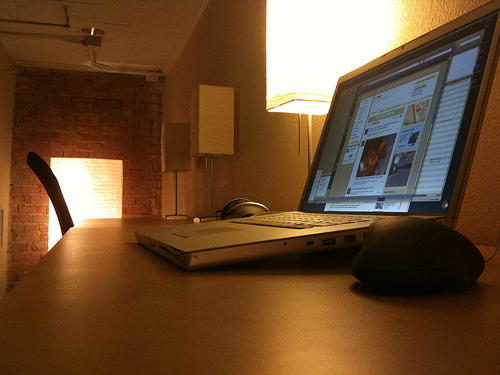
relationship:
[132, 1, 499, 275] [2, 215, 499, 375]
laptop on top of table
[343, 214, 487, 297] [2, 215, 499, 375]
mouse on top of table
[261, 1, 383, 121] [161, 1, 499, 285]
light hanging on wall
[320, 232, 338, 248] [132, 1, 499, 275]
usb drive on side of laptop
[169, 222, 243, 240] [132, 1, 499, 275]
mousepad on edge of laptop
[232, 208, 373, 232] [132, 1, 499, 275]
keyboard on top of laptop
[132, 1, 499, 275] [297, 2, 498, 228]
laptop has monitor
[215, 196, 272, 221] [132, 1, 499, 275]
headphones next to laptop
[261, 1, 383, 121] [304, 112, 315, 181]
light has pole base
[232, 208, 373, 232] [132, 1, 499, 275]
keyboard on front of laptop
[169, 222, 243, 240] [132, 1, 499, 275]
mousepad on front of laptop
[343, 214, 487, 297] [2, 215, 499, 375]
mouse sitting on table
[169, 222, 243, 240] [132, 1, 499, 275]
mousepad on top of laptop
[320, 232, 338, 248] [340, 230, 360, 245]
usb drive next to usb port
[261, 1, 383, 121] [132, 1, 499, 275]
light next to laptop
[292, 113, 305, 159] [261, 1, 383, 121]
pull chain hanging from light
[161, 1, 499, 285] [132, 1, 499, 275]
wall behind laptop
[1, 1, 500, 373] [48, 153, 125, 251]
room has window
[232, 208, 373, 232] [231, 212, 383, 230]
keyboard has keyboard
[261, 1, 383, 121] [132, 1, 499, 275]
light by laptop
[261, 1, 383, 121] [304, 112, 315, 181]
light on top of pole base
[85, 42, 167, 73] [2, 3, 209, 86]
pole on surface of ceiling